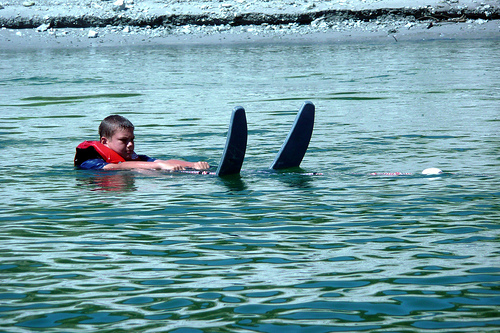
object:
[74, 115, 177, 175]
person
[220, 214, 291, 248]
water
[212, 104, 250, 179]
skis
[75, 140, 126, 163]
life vest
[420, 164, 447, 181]
bobber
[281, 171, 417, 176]
ski rope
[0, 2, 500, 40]
beach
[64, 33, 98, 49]
sand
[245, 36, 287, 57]
shore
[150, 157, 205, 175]
hands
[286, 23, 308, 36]
rock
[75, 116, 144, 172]
boy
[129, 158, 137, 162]
shirt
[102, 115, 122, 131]
hair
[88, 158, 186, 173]
arms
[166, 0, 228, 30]
ledge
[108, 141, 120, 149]
skin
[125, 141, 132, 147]
nose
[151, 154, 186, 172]
bate